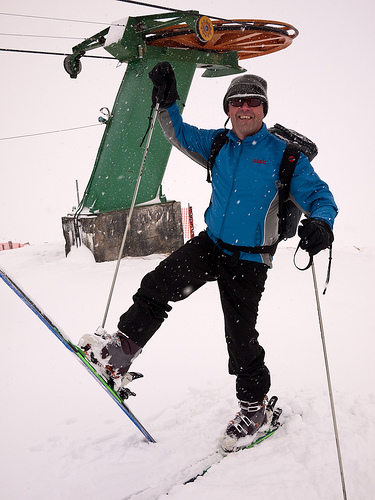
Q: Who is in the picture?
A: A man.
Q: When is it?
A: Day time.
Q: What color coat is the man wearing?
A: Blue.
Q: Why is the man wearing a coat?
A: It is cold.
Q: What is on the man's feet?
A: Skis.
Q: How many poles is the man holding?
A: 2.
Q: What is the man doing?
A: Skiing.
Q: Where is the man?
A: In the snow.